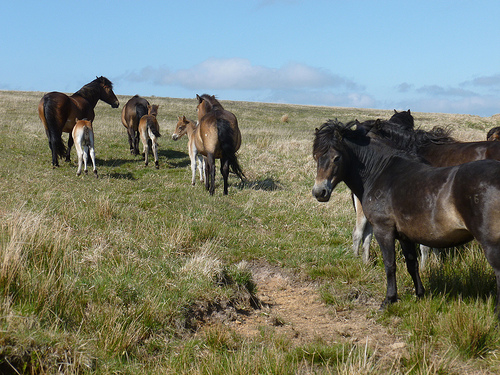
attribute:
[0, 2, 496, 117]
sky — cloudy, blue, clear 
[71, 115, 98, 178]
horse — small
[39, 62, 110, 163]
horse — big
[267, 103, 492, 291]
horses — black, brown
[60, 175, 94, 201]
grass — green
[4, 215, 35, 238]
grass — dead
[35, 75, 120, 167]
horse — adult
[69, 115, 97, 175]
horse — young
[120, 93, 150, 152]
horse — young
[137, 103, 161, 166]
horse — young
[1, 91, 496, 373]
meadow — grassy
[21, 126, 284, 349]
grass — dead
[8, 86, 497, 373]
grass — green, brown, dead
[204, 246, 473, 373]
grass patch — dead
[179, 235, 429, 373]
grass patch — dead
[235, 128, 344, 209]
grass patch — dead